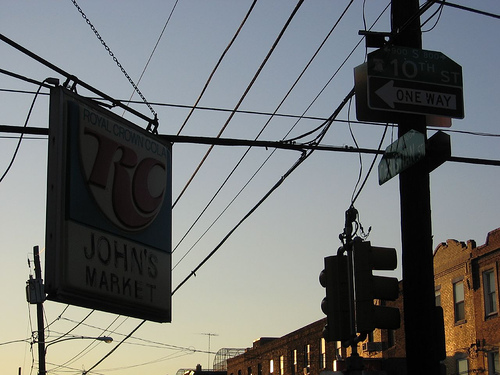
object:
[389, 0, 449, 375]
pole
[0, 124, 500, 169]
utility lines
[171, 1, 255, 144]
wire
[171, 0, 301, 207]
wire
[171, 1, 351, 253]
wire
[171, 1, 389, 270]
wire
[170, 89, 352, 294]
wire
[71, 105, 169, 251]
logo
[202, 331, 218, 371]
antenna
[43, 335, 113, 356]
light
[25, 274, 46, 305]
equipment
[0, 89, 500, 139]
wires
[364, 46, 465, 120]
sign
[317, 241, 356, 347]
traffic lights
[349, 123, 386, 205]
wire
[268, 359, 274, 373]
windows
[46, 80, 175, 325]
sign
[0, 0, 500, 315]
blue sky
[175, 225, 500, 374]
building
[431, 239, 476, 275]
ornamental top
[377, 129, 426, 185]
street sign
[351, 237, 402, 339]
traffic light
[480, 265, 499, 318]
window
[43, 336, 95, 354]
pole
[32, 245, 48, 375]
pole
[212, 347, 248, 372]
greenhouse